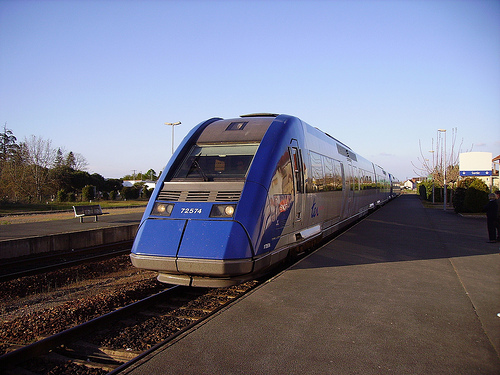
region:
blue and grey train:
[84, 97, 419, 299]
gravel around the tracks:
[33, 271, 178, 362]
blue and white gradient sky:
[30, 8, 458, 207]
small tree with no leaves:
[411, 116, 473, 222]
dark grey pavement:
[188, 223, 473, 373]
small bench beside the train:
[68, 200, 108, 222]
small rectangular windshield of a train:
[185, 136, 258, 188]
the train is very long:
[120, 110, 416, 300]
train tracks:
[4, 287, 262, 370]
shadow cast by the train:
[302, 157, 490, 281]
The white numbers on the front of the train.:
[176, 205, 207, 221]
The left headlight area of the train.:
[149, 198, 172, 214]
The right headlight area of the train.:
[210, 202, 236, 221]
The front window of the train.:
[183, 146, 249, 178]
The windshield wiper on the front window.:
[188, 146, 213, 178]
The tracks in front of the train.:
[6, 284, 229, 373]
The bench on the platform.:
[66, 200, 113, 221]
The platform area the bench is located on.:
[7, 193, 169, 247]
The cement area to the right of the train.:
[272, 175, 498, 373]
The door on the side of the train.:
[287, 140, 309, 227]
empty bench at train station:
[62, 195, 118, 226]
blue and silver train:
[125, 105, 408, 300]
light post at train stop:
[151, 115, 197, 150]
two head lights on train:
[137, 195, 247, 225]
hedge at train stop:
[447, 175, 495, 215]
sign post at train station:
[451, 145, 496, 190]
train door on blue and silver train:
[281, 135, 316, 226]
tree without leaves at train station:
[407, 125, 480, 178]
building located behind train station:
[397, 175, 430, 195]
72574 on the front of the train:
[177, 202, 207, 217]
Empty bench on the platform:
[58, 200, 109, 221]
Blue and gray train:
[135, 118, 394, 294]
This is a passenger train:
[125, 135, 410, 292]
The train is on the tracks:
[117, 110, 424, 303]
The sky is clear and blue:
[9, 6, 498, 201]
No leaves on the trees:
[404, 125, 473, 172]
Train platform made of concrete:
[196, 180, 490, 368]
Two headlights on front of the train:
[139, 201, 250, 228]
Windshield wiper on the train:
[185, 154, 217, 188]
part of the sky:
[211, 42, 271, 110]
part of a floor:
[321, 335, 355, 360]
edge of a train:
[165, 241, 222, 288]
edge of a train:
[95, 295, 147, 340]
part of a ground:
[76, 265, 111, 303]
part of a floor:
[291, 273, 340, 328]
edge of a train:
[225, 206, 265, 299]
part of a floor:
[318, 291, 375, 336]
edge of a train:
[256, 237, 303, 265]